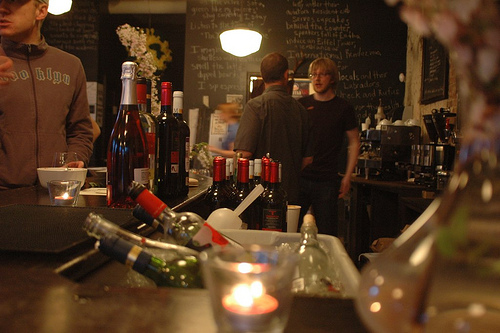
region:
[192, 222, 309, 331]
A glass sits on a table.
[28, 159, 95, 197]
A white bowl is sitting on a table.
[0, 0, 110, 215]
A man is wearing a brown jacket with colored lettering.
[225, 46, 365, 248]
Two men are in the background.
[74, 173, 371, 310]
Some empty bottles are sitting in a container.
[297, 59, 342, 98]
A man is wearing glasses.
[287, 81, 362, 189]
A man is wearing a dark shirt.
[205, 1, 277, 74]
A light hangs from a ceiling.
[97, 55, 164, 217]
A bottle with a red liquid sits on a bar.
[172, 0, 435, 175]
Writing on an object is in the background.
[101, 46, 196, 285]
wine is red with silver top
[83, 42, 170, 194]
wine is red with silver top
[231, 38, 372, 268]
man in black shirt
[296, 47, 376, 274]
man in black shirt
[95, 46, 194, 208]
Four bottles of wine on the bar.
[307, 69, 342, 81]
Glasses on the blond man's face.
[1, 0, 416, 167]
Large chalkboard menu on the walls.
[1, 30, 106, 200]
Brooklyn hoodie on the customer.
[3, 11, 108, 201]
Customer behind the bar.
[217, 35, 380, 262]
Two employees on the inside of the bar.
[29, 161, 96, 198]
White, round bowl on the bar.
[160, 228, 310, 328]
Lit candle on the bar.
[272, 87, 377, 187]
Black t-shirt on the blond man.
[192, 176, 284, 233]
Scoop in the ice.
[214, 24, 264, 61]
Hanging yellow light in a restaurant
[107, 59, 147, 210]
Red bottle of wine with silver top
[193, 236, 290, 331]
Orange candle in a glass candleholder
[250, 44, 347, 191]
Two men talking behind the bar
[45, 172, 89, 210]
Orange candle in a glass candleholder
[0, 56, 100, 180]
Brown jacket with Brooklyn written on it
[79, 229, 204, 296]
Green bottle of wine with black and gold top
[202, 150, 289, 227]
Red bottles of wine with metallic red tops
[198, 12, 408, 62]
Black chalkboard with white writing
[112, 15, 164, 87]
Bouquet of white flowers